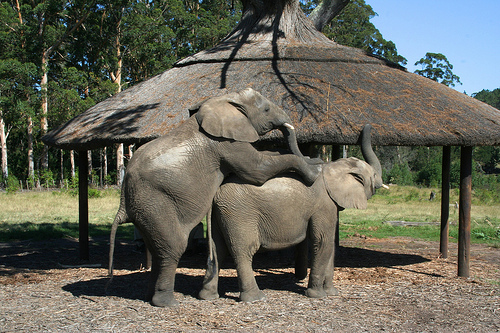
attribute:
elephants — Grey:
[101, 86, 378, 310]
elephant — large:
[107, 86, 325, 308]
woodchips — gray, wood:
[0, 237, 497, 329]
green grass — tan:
[388, 188, 440, 235]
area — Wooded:
[2, 0, 488, 187]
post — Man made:
[445, 129, 497, 275]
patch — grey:
[145, 130, 212, 170]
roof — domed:
[46, 4, 493, 156]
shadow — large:
[0, 221, 445, 302]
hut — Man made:
[43, 0, 498, 279]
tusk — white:
[284, 121, 298, 134]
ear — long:
[195, 95, 261, 142]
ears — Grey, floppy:
[186, 98, 257, 145]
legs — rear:
[139, 233, 193, 310]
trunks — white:
[1, 51, 132, 195]